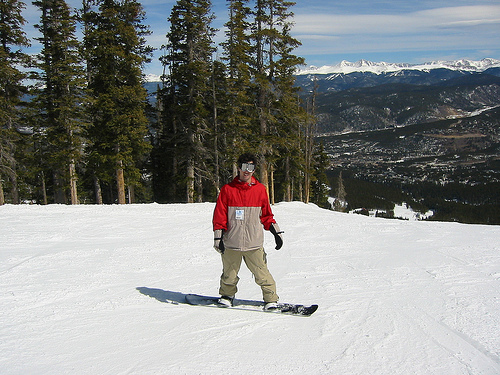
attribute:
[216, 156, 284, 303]
man — snowboarder, posing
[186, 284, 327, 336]
snowboard — long, black, white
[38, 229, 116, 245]
ground — snow, flat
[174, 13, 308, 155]
trees — green, pine, evergreen, tall, narrow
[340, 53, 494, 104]
mountains — distant, large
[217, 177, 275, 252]
jacket — beige, red, tan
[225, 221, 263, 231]
waist — fitted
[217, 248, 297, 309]
pants — khaki, baggy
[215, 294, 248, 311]
straps — white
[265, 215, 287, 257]
gloves — beige, black, gray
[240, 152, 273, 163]
hair — black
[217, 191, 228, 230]
sleeve — red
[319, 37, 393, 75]
sky — blue